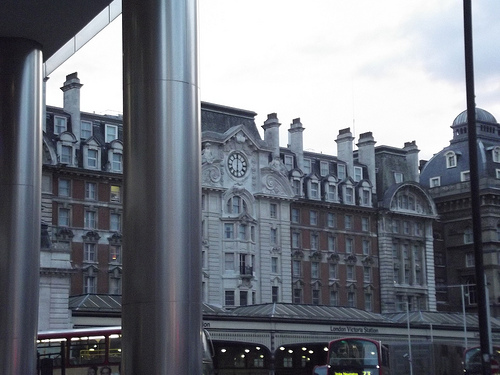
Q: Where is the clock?
A: On the buiding.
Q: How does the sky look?
A: Overcast.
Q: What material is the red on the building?
A: Brick.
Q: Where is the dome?
A: On the left top side of the building.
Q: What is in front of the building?
A: A bus.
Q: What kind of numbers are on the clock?
A: Roman numerals.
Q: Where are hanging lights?
A: In the building's entryway.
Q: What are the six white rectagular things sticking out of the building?
A: Chimneys.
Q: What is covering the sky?
A: Clouds.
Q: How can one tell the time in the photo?
A: Clock on building.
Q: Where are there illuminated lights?
A: Bottom of building.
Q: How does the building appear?
A: Old and ornate.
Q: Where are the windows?
A: On building.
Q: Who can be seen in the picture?
A: No one.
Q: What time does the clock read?
A: 6:00.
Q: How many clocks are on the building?
A: One.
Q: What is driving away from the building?
A: A bus.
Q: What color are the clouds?
A: White.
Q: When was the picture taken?
A: 6:00.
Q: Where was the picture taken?
A: On a city street.